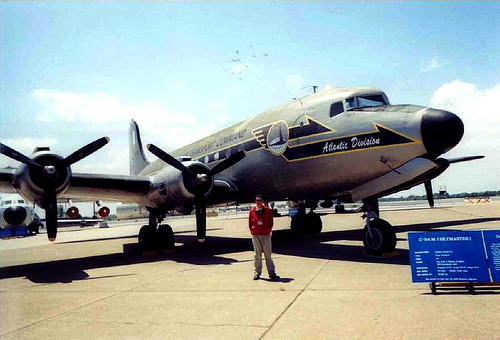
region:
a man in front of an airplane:
[10, 13, 487, 290]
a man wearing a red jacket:
[237, 189, 295, 291]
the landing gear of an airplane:
[353, 196, 400, 263]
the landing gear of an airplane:
[286, 196, 323, 243]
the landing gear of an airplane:
[126, 206, 179, 251]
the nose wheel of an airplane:
[353, 193, 400, 255]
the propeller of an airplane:
[140, 139, 248, 249]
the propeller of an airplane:
[0, 124, 110, 241]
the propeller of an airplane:
[419, 153, 492, 205]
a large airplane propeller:
[147, 141, 253, 244]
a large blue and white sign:
[405, 230, 489, 294]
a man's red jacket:
[246, 205, 274, 232]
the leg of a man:
[257, 233, 277, 274]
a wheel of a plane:
[357, 215, 397, 252]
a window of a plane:
[354, 92, 386, 109]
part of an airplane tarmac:
[0, 225, 404, 339]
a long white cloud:
[11, 80, 195, 144]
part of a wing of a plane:
[0, 168, 149, 208]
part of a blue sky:
[24, 0, 121, 47]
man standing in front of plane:
[248, 195, 282, 281]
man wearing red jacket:
[246, 196, 273, 236]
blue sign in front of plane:
[406, 227, 498, 284]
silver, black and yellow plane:
[0, 79, 483, 251]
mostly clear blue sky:
[1, 3, 499, 192]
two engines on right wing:
[0, 132, 250, 242]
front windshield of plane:
[327, 88, 392, 119]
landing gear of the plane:
[138, 211, 397, 258]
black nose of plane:
[421, 103, 468, 160]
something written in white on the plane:
[318, 135, 390, 154]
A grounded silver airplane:
[1, 85, 484, 256]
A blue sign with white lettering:
[408, 230, 499, 291]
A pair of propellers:
[0, 135, 246, 240]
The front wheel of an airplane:
[362, 218, 397, 255]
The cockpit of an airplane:
[324, 91, 389, 117]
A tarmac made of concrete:
[1, 200, 498, 338]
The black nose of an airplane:
[419, 107, 465, 157]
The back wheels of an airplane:
[136, 212, 321, 252]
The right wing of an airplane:
[0, 167, 237, 207]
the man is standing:
[244, 188, 289, 279]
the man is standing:
[232, 185, 287, 302]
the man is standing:
[237, 184, 294, 294]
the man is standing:
[231, 181, 283, 298]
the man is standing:
[232, 185, 287, 295]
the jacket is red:
[236, 208, 282, 238]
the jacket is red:
[235, 202, 280, 244]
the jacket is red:
[242, 207, 277, 244]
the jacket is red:
[227, 196, 282, 242]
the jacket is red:
[235, 204, 287, 242]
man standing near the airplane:
[246, 191, 286, 278]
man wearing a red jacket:
[237, 206, 276, 236]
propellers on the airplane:
[141, 138, 250, 243]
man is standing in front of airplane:
[245, 193, 280, 282]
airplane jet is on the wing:
[0, 134, 109, 240]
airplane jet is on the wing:
[149, 142, 249, 242]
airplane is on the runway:
[0, 85, 485, 257]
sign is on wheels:
[407, 225, 498, 284]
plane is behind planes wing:
[0, 191, 103, 235]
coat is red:
[249, 205, 276, 232]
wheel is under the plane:
[361, 218, 396, 257]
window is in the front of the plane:
[329, 93, 386, 117]